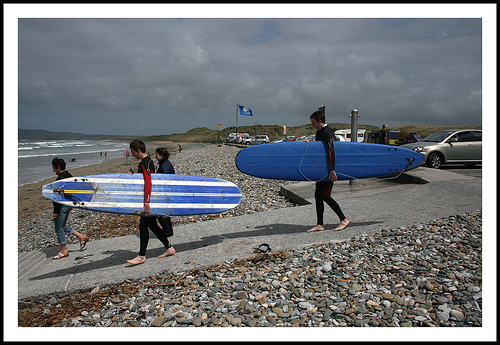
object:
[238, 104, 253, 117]
flag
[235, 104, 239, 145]
pole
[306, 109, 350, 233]
man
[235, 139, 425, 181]
surfboard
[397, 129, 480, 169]
car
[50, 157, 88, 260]
person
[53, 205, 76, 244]
jeans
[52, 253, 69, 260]
sandals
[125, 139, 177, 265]
man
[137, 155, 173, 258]
wet suit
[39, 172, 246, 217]
surfboard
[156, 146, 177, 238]
woman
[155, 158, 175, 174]
shirt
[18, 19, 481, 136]
sky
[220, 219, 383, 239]
shadow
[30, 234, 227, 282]
shadow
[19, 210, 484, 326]
rocks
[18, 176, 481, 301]
walkway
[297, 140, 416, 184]
leash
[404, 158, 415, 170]
leash holder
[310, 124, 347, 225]
wet suit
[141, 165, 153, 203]
sleeve